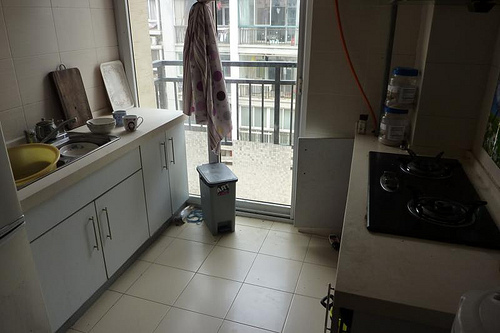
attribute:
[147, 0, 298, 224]
door — sliding, glass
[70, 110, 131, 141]
bowl — white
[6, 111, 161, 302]
sink — full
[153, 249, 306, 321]
tiles — white, large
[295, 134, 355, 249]
cabinet door — white, open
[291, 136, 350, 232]
door — open, cupboard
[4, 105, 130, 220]
sink — kitchen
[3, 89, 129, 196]
dishes — dirty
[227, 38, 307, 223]
door — glass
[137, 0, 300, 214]
door — glass, sliding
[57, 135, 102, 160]
dishes — dirty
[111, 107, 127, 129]
cup — blue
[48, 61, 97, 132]
board — cutting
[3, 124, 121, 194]
sink — kitchen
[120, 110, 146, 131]
mug — coffee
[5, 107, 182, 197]
counter — kitchen